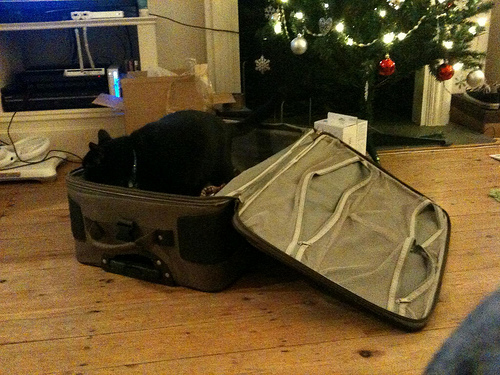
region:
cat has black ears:
[90, 134, 121, 177]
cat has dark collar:
[107, 134, 150, 184]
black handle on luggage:
[85, 231, 160, 263]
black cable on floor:
[6, 101, 93, 188]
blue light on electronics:
[106, 68, 143, 128]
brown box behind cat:
[110, 71, 204, 140]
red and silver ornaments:
[375, 41, 482, 103]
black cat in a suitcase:
[49, 90, 475, 326]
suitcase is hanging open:
[61, 92, 450, 338]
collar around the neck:
[119, 140, 145, 189]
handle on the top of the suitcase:
[80, 221, 163, 256]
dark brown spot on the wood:
[356, 338, 380, 363]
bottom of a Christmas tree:
[245, 0, 498, 119]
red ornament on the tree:
[377, 52, 397, 75]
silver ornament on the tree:
[289, 34, 308, 59]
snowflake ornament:
[251, 52, 273, 77]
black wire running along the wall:
[146, 9, 241, 44]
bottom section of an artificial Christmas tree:
[237, 0, 495, 162]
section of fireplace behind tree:
[237, 1, 433, 123]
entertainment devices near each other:
[3, 10, 124, 110]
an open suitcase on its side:
[65, 103, 452, 325]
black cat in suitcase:
[78, 108, 263, 198]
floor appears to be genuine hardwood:
[0, 143, 496, 365]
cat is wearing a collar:
[125, 134, 140, 189]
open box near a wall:
[91, 49, 234, 137]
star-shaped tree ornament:
[250, 52, 270, 75]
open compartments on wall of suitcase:
[237, 131, 450, 326]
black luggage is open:
[105, 101, 417, 301]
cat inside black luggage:
[82, 111, 242, 212]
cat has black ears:
[76, 131, 120, 201]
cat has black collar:
[119, 131, 146, 207]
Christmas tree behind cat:
[268, 0, 459, 94]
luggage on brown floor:
[75, 74, 362, 289]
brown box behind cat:
[110, 49, 204, 129]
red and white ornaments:
[356, 41, 496, 116]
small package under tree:
[415, 51, 460, 140]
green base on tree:
[318, 66, 450, 172]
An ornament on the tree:
[288, 33, 307, 55]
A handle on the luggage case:
[86, 219, 155, 256]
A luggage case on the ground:
[66, 117, 451, 331]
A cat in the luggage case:
[85, 83, 292, 194]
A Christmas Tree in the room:
[253, 0, 492, 163]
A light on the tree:
[381, 32, 394, 46]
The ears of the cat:
[92, 124, 109, 150]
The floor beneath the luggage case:
[1, 143, 498, 374]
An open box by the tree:
[121, 70, 210, 132]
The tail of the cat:
[229, 83, 312, 134]